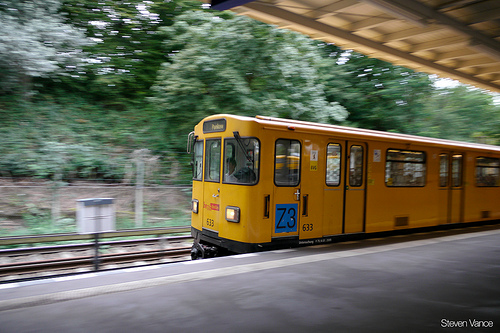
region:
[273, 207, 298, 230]
Z3 printed on train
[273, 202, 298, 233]
blue square printed on train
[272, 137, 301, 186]
first side window of train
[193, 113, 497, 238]
the yellow train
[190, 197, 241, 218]
the two front lights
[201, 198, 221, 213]
the red painted on the front of the train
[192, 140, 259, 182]
the three windows on front of train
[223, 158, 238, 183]
the driver in front of train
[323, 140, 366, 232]
the first set of doors on train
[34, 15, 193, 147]
the trees on other side of train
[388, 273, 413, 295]
part of a floor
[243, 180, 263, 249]
edge of a train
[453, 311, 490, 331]
part of a graphic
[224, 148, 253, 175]
part of a window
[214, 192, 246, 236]
part of a headlight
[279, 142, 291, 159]
part of a window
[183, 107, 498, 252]
a passenger train sitting on the track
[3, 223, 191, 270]
the train tracks on the ground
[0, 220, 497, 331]
the platform next to the train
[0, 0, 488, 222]
the trees next to the track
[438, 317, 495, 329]
the writing in the corner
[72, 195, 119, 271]
the sign next to the platform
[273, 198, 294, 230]
the blue sign on the train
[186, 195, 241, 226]
the headlights on the train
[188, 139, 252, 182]
the front windows of the train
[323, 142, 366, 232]
the doors of the train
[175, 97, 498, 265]
yellow train in a station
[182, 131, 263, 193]
front windshield on a train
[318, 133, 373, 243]
doors on a train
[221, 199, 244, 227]
front lights on a train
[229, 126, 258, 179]
windshield wiper on a train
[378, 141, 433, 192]
side window on a train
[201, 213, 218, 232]
number on the front of a train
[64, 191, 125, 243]
white box on a post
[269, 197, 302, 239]
blue and black notation on a train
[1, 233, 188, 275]
pair of train tracks on the ground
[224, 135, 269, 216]
edge of a train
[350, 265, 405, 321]
part of a floor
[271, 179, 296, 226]
part of a door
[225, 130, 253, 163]
part of a window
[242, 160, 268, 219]
edge of a train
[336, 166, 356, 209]
edge of a door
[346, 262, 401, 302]
part of a shade